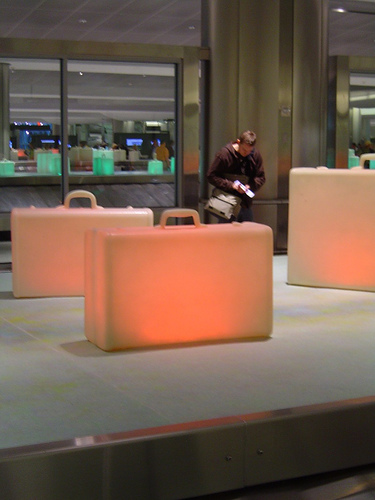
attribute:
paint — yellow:
[284, 297, 359, 348]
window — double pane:
[0, 57, 176, 241]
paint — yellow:
[11, 298, 96, 394]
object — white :
[232, 182, 273, 206]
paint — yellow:
[282, 311, 351, 330]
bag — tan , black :
[203, 172, 251, 221]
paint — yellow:
[10, 365, 86, 405]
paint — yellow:
[274, 311, 362, 340]